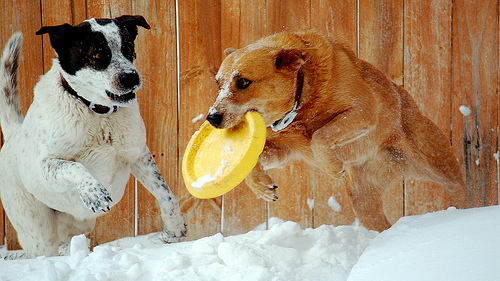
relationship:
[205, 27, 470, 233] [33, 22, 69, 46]
brown dog has ear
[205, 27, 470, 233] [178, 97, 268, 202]
brown dog playing frisbee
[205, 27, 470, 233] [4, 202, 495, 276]
brown dog in snow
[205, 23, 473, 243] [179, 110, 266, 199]
brown dog with disc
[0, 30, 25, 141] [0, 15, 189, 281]
tail of dog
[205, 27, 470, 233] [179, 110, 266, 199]
brown dog with disc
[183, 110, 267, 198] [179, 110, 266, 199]
disc with disc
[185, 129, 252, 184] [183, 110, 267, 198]
space in disc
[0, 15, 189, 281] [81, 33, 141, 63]
dog with black eyes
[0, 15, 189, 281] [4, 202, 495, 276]
dog playing on top of snow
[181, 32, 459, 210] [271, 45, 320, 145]
dog wearing a collar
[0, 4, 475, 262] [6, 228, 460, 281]
dogs playing in snow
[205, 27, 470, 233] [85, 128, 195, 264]
brown dog with yellow fur standing on hind legs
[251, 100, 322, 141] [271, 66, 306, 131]
collar on dog to use for collar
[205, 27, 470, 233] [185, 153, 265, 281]
brown dog mouth to grab frisbees and eat food and drink water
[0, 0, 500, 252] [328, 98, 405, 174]
fence behind dog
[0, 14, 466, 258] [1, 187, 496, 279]
dogs are playing in snow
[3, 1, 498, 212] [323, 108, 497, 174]
fence made out of wood